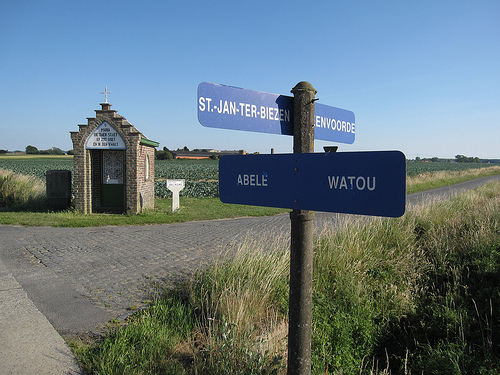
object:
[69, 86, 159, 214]
building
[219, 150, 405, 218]
sign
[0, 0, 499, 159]
sky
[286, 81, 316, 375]
pole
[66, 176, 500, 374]
grass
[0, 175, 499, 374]
road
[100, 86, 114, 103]
cross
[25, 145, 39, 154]
tree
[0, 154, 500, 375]
field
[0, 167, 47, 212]
bush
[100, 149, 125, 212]
door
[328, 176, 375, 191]
letter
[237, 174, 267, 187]
print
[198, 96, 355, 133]
print